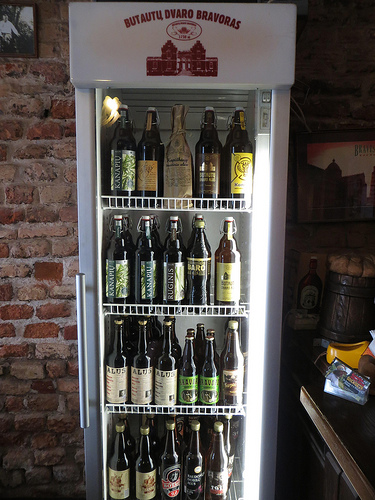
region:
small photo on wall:
[0, 3, 43, 65]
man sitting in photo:
[1, 8, 21, 45]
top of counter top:
[349, 425, 366, 450]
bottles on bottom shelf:
[110, 420, 232, 499]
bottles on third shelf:
[102, 316, 247, 406]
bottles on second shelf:
[102, 212, 246, 309]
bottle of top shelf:
[101, 96, 256, 209]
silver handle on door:
[69, 266, 95, 435]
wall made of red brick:
[13, 305, 63, 338]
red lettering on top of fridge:
[113, 10, 246, 34]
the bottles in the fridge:
[102, 103, 249, 492]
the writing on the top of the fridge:
[123, 6, 242, 76]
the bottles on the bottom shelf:
[117, 414, 238, 495]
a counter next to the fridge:
[290, 340, 369, 486]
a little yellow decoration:
[322, 341, 367, 368]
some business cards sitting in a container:
[329, 360, 368, 401]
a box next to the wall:
[298, 253, 322, 312]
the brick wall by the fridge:
[3, 5, 79, 482]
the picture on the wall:
[1, 1, 36, 59]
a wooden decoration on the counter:
[320, 253, 370, 343]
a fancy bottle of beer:
[109, 100, 134, 206]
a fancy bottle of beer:
[137, 105, 162, 206]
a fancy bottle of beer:
[197, 105, 222, 210]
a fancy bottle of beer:
[223, 106, 253, 206]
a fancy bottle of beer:
[106, 215, 131, 312]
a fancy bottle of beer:
[136, 215, 159, 311]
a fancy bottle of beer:
[107, 316, 130, 403]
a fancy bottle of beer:
[130, 316, 151, 408]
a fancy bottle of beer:
[155, 318, 178, 410]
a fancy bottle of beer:
[179, 334, 197, 410]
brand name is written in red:
[121, 8, 238, 77]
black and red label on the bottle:
[160, 463, 180, 496]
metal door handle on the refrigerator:
[76, 271, 90, 428]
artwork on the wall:
[1, 0, 38, 59]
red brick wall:
[1, 1, 71, 496]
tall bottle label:
[135, 467, 155, 496]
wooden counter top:
[296, 368, 372, 494]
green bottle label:
[199, 376, 218, 404]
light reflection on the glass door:
[102, 96, 121, 127]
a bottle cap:
[184, 336, 194, 341]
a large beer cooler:
[67, 2, 297, 499]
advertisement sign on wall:
[294, 130, 372, 222]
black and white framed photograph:
[0, 2, 36, 58]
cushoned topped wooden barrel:
[318, 249, 373, 352]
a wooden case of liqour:
[289, 247, 332, 332]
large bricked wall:
[0, 0, 373, 498]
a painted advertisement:
[68, 3, 295, 87]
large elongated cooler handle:
[72, 271, 90, 429]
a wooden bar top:
[281, 299, 374, 498]